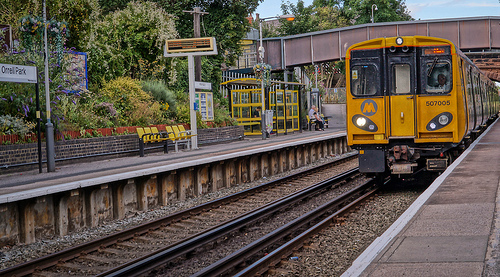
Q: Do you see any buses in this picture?
A: No, there are no buses.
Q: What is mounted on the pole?
A: The sign is mounted on the pole.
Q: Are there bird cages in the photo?
A: No, there are no bird cages.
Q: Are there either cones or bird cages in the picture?
A: No, there are no bird cages or cones.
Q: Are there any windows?
A: Yes, there is a window.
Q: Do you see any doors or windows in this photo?
A: Yes, there is a window.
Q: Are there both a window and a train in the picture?
A: Yes, there are both a window and a train.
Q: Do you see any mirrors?
A: No, there are no mirrors.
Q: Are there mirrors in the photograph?
A: No, there are no mirrors.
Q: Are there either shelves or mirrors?
A: No, there are no mirrors or shelves.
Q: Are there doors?
A: Yes, there is a door.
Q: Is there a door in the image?
A: Yes, there is a door.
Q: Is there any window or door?
A: Yes, there is a door.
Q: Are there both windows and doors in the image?
A: Yes, there are both a door and a window.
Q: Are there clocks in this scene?
A: No, there are no clocks.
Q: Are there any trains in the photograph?
A: Yes, there is a train.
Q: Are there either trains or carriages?
A: Yes, there is a train.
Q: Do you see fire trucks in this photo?
A: No, there are no fire trucks.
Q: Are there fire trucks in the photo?
A: No, there are no fire trucks.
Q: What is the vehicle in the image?
A: The vehicle is a train.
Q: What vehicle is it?
A: The vehicle is a train.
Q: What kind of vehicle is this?
A: That is a train.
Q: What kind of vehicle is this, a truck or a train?
A: That is a train.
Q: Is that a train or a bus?
A: That is a train.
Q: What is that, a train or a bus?
A: That is a train.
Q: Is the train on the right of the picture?
A: Yes, the train is on the right of the image.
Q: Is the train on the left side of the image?
A: No, the train is on the right of the image.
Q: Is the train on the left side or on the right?
A: The train is on the right of the image.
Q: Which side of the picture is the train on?
A: The train is on the right of the image.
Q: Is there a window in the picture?
A: Yes, there is a window.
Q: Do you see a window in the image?
A: Yes, there is a window.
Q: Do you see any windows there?
A: Yes, there is a window.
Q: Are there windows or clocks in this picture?
A: Yes, there is a window.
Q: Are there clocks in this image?
A: No, there are no clocks.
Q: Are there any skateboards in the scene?
A: No, there are no skateboards.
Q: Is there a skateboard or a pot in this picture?
A: No, there are no skateboards or pots.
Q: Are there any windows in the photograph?
A: Yes, there is a window.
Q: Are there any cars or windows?
A: Yes, there is a window.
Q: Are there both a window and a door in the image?
A: Yes, there are both a window and a door.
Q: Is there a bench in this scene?
A: Yes, there is a bench.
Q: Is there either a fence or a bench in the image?
A: Yes, there is a bench.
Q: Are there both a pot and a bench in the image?
A: No, there is a bench but no pots.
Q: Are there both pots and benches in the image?
A: No, there is a bench but no pots.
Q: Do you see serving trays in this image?
A: No, there are no serving trays.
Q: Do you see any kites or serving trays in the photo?
A: No, there are no serving trays or kites.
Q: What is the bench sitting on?
A: The bench is sitting on the sidewalk.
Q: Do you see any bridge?
A: Yes, there is a bridge.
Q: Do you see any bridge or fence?
A: Yes, there is a bridge.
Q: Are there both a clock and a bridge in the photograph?
A: No, there is a bridge but no clocks.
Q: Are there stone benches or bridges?
A: Yes, there is a stone bridge.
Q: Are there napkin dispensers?
A: No, there are no napkin dispensers.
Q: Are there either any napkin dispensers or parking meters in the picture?
A: No, there are no napkin dispensers or parking meters.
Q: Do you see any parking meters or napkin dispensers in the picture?
A: No, there are no napkin dispensers or parking meters.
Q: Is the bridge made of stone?
A: Yes, the bridge is made of stone.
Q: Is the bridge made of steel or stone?
A: The bridge is made of stone.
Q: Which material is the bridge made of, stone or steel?
A: The bridge is made of stone.